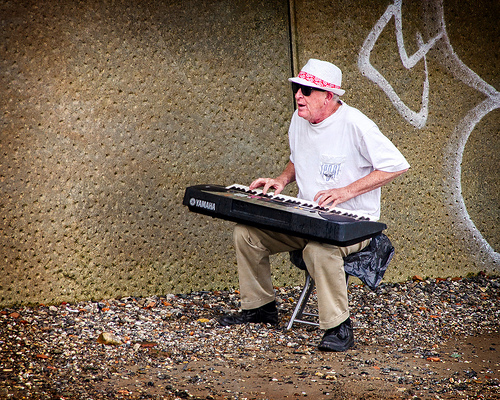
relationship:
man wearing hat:
[212, 43, 414, 350] [283, 51, 357, 108]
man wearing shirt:
[212, 43, 414, 350] [281, 96, 416, 234]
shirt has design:
[281, 96, 416, 234] [316, 156, 347, 189]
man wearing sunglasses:
[212, 43, 414, 350] [287, 83, 331, 102]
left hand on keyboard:
[307, 183, 351, 213] [177, 171, 392, 262]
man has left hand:
[212, 43, 414, 350] [307, 183, 351, 213]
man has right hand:
[212, 43, 414, 350] [246, 172, 287, 201]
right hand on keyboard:
[246, 172, 287, 201] [177, 171, 392, 262]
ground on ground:
[0, 273, 500, 400] [0, 268, 498, 398]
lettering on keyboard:
[193, 195, 221, 216] [177, 171, 392, 262]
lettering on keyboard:
[190, 198, 216, 211] [177, 171, 392, 262]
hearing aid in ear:
[323, 91, 338, 104] [324, 91, 337, 108]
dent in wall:
[281, 1, 305, 117] [1, 1, 497, 314]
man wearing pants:
[212, 43, 414, 350] [219, 218, 383, 337]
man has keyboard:
[212, 43, 414, 350] [177, 171, 392, 262]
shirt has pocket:
[281, 96, 416, 234] [318, 156, 344, 170]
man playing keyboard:
[212, 43, 414, 350] [177, 171, 392, 262]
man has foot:
[212, 43, 414, 350] [217, 300, 284, 331]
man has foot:
[212, 43, 414, 350] [319, 317, 359, 357]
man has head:
[212, 43, 414, 350] [281, 54, 351, 129]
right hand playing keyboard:
[246, 172, 287, 201] [177, 171, 392, 262]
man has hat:
[212, 43, 414, 350] [283, 51, 357, 108]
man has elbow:
[212, 43, 414, 350] [397, 160, 417, 178]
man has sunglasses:
[212, 43, 414, 350] [287, 83, 331, 102]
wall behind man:
[1, 1, 497, 314] [212, 43, 414, 350]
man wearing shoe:
[212, 43, 414, 350] [311, 317, 357, 355]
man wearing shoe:
[212, 43, 414, 350] [213, 301, 288, 340]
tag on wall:
[353, 1, 499, 276] [1, 1, 497, 314]